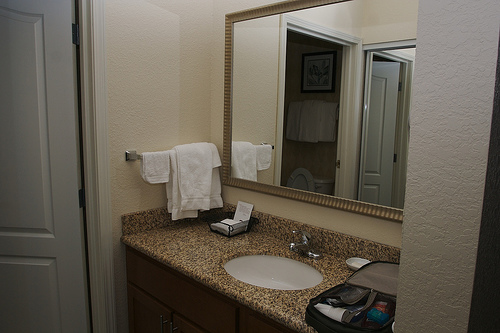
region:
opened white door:
[4, 2, 69, 329]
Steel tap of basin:
[291, 228, 323, 258]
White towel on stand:
[171, 146, 216, 216]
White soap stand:
[346, 253, 368, 268]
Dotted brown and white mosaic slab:
[150, 228, 221, 261]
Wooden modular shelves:
[128, 268, 169, 330]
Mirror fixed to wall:
[235, 20, 389, 176]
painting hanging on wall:
[299, 50, 339, 94]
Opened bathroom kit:
[321, 272, 392, 330]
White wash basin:
[235, 256, 307, 285]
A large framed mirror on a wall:
[220, 1, 405, 223]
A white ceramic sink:
[221, 248, 323, 299]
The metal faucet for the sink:
[281, 228, 324, 260]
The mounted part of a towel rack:
[120, 146, 143, 163]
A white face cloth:
[139, 150, 170, 187]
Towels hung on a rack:
[169, 140, 226, 222]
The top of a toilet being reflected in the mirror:
[285, 166, 335, 192]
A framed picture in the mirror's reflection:
[298, 49, 334, 94]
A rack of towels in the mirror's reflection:
[284, 98, 341, 147]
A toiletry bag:
[303, 255, 398, 329]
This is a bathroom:
[9, 4, 498, 331]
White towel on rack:
[125, 135, 233, 230]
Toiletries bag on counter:
[303, 245, 421, 326]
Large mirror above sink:
[212, 1, 435, 232]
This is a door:
[1, 3, 99, 328]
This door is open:
[6, 5, 117, 330]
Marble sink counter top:
[99, 183, 409, 332]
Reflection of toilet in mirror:
[279, 154, 348, 196]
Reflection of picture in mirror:
[294, 42, 344, 101]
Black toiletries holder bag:
[303, 246, 403, 331]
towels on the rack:
[118, 132, 238, 214]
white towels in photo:
[133, 128, 232, 221]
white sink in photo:
[206, 234, 322, 317]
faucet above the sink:
[252, 220, 332, 287]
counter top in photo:
[163, 232, 223, 272]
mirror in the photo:
[227, 20, 400, 159]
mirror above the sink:
[217, 24, 398, 184]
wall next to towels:
[103, 25, 204, 98]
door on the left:
[1, 18, 124, 294]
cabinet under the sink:
[146, 299, 190, 331]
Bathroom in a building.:
[5, 2, 485, 332]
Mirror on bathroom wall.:
[213, 3, 433, 227]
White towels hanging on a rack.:
[118, 140, 225, 224]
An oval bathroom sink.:
[217, 244, 327, 296]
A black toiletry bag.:
[302, 255, 403, 331]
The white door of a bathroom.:
[1, 2, 130, 331]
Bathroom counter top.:
[117, 199, 408, 326]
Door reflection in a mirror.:
[268, 11, 420, 216]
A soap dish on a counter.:
[340, 252, 367, 271]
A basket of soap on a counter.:
[203, 198, 255, 240]